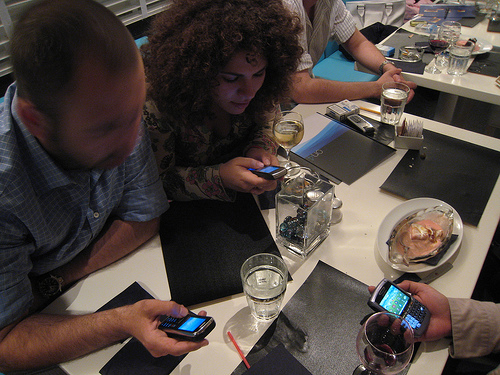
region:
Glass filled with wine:
[272, 109, 302, 173]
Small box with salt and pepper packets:
[390, 113, 432, 150]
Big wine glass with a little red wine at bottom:
[353, 312, 415, 373]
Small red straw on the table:
[223, 329, 250, 372]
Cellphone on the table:
[345, 112, 377, 139]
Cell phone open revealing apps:
[369, 277, 446, 337]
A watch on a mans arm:
[372, 58, 396, 73]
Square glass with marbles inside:
[271, 173, 337, 256]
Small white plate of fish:
[372, 198, 467, 280]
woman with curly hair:
[188, 14, 208, 53]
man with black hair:
[51, 67, 66, 79]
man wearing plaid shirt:
[11, 177, 48, 224]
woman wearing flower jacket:
[163, 141, 188, 161]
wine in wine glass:
[275, 124, 304, 146]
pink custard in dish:
[407, 222, 432, 248]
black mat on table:
[321, 283, 356, 327]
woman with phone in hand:
[240, 150, 287, 194]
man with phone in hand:
[359, 270, 464, 332]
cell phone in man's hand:
[151, 307, 215, 341]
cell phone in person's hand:
[366, 280, 433, 335]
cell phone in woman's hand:
[250, 163, 288, 182]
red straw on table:
[220, 327, 263, 371]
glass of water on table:
[241, 245, 287, 329]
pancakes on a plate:
[373, 192, 465, 278]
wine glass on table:
[271, 111, 305, 155]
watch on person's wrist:
[32, 271, 63, 297]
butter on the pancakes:
[407, 223, 435, 241]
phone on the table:
[349, 108, 376, 135]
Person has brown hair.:
[181, 18, 215, 91]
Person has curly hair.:
[180, 41, 215, 91]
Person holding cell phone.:
[231, 151, 292, 193]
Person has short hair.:
[35, 34, 93, 84]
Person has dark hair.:
[51, 45, 96, 89]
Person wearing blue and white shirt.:
[20, 178, 52, 211]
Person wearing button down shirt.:
[78, 189, 117, 259]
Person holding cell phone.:
[380, 270, 435, 347]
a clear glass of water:
[236, 250, 288, 321]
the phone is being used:
[365, 280, 431, 341]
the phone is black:
[157, 312, 218, 338]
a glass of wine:
[273, 110, 303, 180]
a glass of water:
[376, 80, 407, 141]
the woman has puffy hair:
[140, 0, 300, 205]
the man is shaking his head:
[1, 2, 207, 372]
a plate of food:
[375, 195, 465, 275]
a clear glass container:
[270, 170, 330, 255]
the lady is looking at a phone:
[141, 3, 306, 208]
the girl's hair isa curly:
[138, 9, 322, 140]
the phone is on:
[160, 282, 211, 368]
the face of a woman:
[210, 35, 264, 127]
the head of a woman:
[152, 11, 299, 155]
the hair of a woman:
[137, 10, 229, 125]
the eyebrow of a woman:
[214, 65, 248, 80]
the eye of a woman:
[223, 72, 246, 87]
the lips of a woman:
[225, 97, 257, 114]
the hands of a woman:
[217, 145, 284, 204]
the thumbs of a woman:
[247, 151, 274, 171]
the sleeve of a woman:
[152, 151, 236, 214]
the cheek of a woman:
[212, 89, 239, 104]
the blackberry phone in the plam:
[363, 279, 430, 338]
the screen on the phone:
[374, 280, 409, 315]